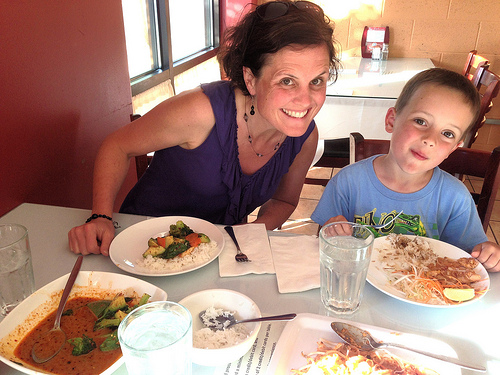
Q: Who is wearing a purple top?
A: The woman.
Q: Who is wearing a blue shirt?
A: The young boy.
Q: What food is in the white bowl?
A: White rice.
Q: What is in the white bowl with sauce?
A: Green vegetables.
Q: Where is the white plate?
A: On the table.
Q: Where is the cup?
A: On the table.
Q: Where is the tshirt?
A: On the boy.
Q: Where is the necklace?
A: On the woman.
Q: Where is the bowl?
A: On the table.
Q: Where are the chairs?
A: At the tables.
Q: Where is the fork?
A: On the table.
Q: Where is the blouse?
A: On the woman.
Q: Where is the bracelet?
A: On the wrist.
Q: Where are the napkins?
A: On the table.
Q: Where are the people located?
A: At a restaurant.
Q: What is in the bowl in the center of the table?
A: Rice.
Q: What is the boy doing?
A: Eating.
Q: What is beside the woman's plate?
A: A fork.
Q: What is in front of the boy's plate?
A: A glass of water.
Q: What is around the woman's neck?
A: A necklace.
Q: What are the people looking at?
A: The camera.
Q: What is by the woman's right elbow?
A: A wall.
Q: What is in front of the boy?
A: A plate of food.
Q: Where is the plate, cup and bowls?
A: On a dining table.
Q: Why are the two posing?
A: For a camera.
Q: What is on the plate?
A: Vegetables and rice.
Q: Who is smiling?
A: A middle aged woman.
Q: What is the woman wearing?
A: A sleeveless purple top.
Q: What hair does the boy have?
A: Brown short hair.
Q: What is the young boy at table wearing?
A: Blue tshirt.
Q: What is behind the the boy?
A: An empty table with a white table cloth.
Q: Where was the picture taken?
A: A restaurant.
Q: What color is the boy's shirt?
A: Blue.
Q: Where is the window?
A: Behind the woman.